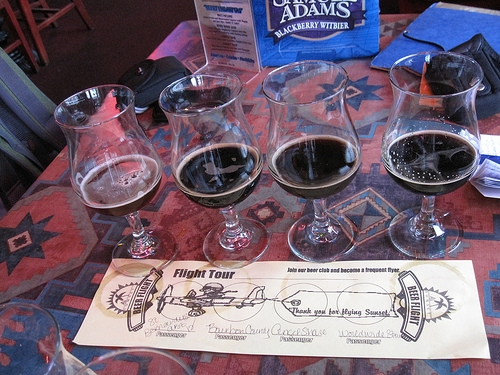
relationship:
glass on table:
[157, 68, 273, 271] [1, 10, 499, 373]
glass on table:
[230, 20, 382, 260] [39, 20, 456, 367]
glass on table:
[378, 49, 485, 259] [1, 10, 499, 373]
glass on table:
[258, 59, 360, 264] [1, 10, 499, 373]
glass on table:
[50, 84, 165, 274] [1, 10, 499, 373]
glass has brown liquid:
[378, 49, 485, 259] [376, 126, 481, 199]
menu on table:
[72, 257, 492, 358] [1, 10, 499, 373]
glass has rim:
[378, 49, 485, 259] [273, 67, 279, 69]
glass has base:
[258, 59, 360, 264] [283, 206, 358, 271]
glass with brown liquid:
[51, 84, 179, 277] [376, 127, 480, 199]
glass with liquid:
[157, 68, 273, 271] [271, 135, 358, 200]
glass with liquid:
[258, 59, 360, 264] [173, 141, 263, 210]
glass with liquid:
[378, 49, 485, 259] [80, 150, 162, 217]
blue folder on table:
[367, 0, 497, 80] [1, 10, 499, 373]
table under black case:
[1, 10, 499, 373] [419, 31, 498, 126]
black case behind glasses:
[111, 53, 205, 126] [56, 80, 478, 247]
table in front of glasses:
[1, 10, 498, 375] [381, 51, 482, 258]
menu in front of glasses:
[72, 257, 492, 358] [260, 61, 361, 261]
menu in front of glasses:
[72, 257, 492, 358] [159, 71, 271, 268]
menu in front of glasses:
[72, 257, 492, 358] [53, 83, 179, 277]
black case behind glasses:
[419, 31, 498, 126] [39, 48, 482, 263]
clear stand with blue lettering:
[195, 60, 255, 80] [209, 52, 255, 64]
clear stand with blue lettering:
[195, 60, 255, 80] [203, 2, 242, 14]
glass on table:
[51, 84, 179, 277] [1, 10, 499, 373]